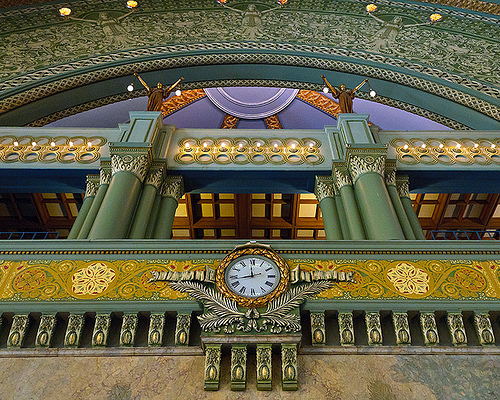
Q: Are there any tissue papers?
A: No, there are no tissue papers.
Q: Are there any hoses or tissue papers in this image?
A: No, there are no tissue papers or hoses.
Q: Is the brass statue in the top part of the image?
A: Yes, the statue is in the top of the image.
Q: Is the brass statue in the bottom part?
A: No, the statue is in the top of the image.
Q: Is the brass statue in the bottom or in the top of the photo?
A: The statue is in the top of the image.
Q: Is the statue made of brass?
A: Yes, the statue is made of brass.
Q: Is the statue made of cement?
A: No, the statue is made of brass.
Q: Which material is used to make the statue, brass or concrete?
A: The statue is made of brass.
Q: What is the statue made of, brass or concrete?
A: The statue is made of brass.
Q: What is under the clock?
A: The leaves are under the clock.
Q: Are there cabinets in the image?
A: No, there are no cabinets.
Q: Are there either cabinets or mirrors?
A: No, there are no cabinets or mirrors.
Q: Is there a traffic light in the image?
A: No, there are no traffic lights.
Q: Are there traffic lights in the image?
A: No, there are no traffic lights.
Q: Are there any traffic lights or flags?
A: No, there are no traffic lights or flags.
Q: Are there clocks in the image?
A: Yes, there is a clock.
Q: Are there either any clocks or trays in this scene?
A: Yes, there is a clock.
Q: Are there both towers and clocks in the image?
A: No, there is a clock but no towers.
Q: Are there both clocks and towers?
A: No, there is a clock but no towers.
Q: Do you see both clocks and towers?
A: No, there is a clock but no towers.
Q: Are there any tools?
A: No, there are no tools.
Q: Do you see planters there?
A: No, there are no planters.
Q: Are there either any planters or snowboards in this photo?
A: No, there are no planters or snowboards.